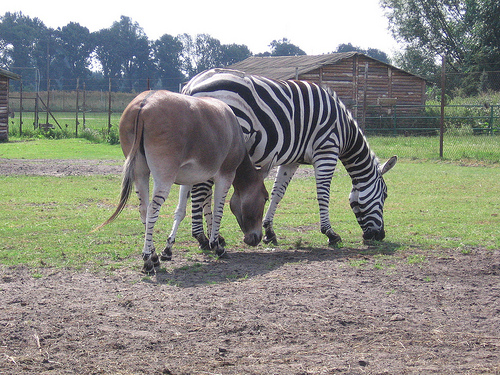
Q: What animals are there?
A: Zebras.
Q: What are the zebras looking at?
A: The ground.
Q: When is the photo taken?
A: Day time.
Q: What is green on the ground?
A: The grass.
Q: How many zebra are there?
A: Two.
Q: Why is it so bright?
A: Sunny.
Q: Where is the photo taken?
A: The field.